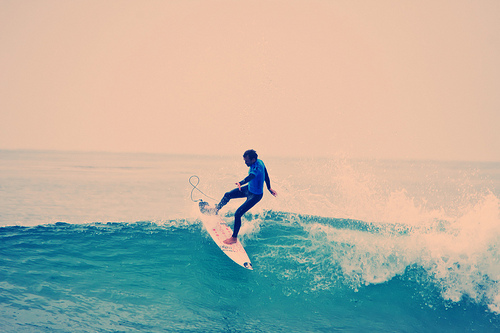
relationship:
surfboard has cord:
[193, 199, 255, 272] [188, 173, 219, 202]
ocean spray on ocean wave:
[52, 217, 359, 322] [4, 170, 476, 309]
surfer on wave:
[208, 113, 292, 278] [318, 180, 447, 275]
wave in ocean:
[3, 212, 495, 329] [3, 146, 495, 328]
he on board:
[200, 147, 278, 244] [158, 184, 263, 291]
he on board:
[200, 147, 278, 244] [194, 197, 253, 273]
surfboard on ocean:
[193, 195, 258, 286] [2, 210, 484, 322]